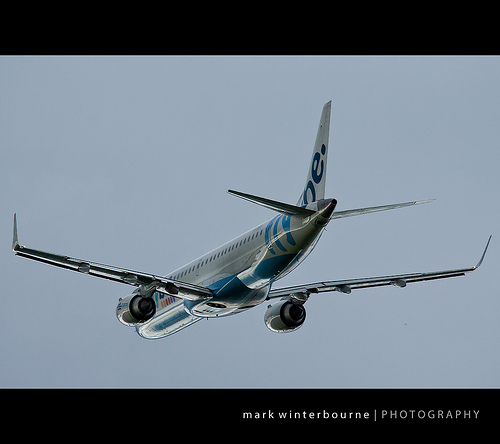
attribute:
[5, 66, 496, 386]
clouds — white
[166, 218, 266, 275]
windows — passenger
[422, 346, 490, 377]
clouds — white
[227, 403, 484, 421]
text — white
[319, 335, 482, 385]
clouds — white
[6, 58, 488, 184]
sky — blue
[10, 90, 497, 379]
jet — blue, white, passenger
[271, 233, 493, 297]
wing — right wing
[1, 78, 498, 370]
plane — blue, silver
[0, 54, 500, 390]
sky — blue